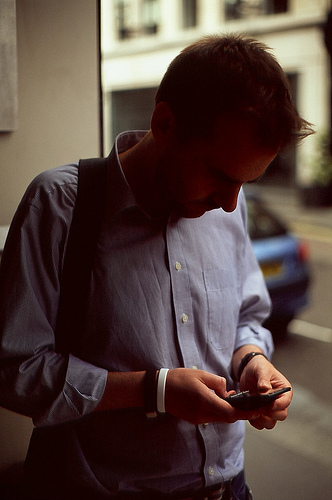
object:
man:
[0, 35, 316, 500]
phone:
[221, 380, 291, 414]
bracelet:
[154, 365, 168, 412]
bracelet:
[143, 364, 157, 416]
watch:
[234, 349, 267, 382]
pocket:
[201, 265, 241, 355]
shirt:
[0, 126, 273, 486]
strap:
[53, 156, 100, 358]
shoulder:
[17, 161, 125, 220]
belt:
[124, 481, 247, 499]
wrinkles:
[111, 257, 171, 364]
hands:
[164, 365, 260, 428]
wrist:
[154, 366, 171, 415]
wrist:
[235, 350, 264, 389]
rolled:
[32, 347, 109, 429]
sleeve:
[1, 159, 108, 427]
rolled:
[231, 317, 274, 363]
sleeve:
[232, 226, 275, 364]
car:
[238, 192, 312, 337]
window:
[181, 2, 200, 30]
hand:
[237, 352, 293, 431]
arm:
[18, 347, 169, 422]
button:
[171, 260, 181, 272]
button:
[180, 312, 189, 324]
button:
[187, 362, 199, 374]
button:
[200, 419, 211, 430]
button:
[206, 464, 215, 482]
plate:
[258, 258, 284, 279]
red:
[297, 240, 306, 265]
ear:
[149, 99, 175, 152]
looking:
[206, 158, 264, 187]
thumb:
[198, 369, 228, 399]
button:
[230, 389, 250, 401]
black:
[78, 161, 96, 211]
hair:
[154, 30, 317, 158]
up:
[243, 35, 275, 57]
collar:
[97, 149, 138, 228]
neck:
[116, 129, 174, 220]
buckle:
[240, 349, 255, 367]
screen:
[247, 385, 285, 393]